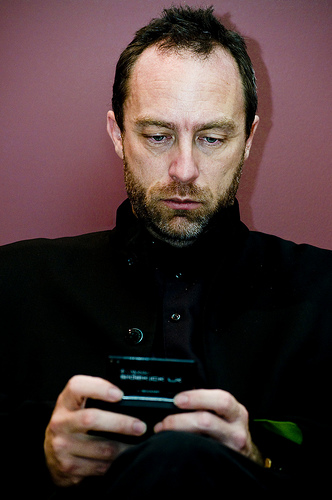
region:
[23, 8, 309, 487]
a man holding an electronic device in his hand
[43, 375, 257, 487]
the hands of a man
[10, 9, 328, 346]
a man wearing a black coat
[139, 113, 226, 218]
the face of a man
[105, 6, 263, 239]
the head of a man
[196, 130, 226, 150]
the eye of a man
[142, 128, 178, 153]
the eye of a man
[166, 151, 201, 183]
the nose of a man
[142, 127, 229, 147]
the eyes of a man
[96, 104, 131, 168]
the ear of a man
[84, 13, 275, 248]
man has a beard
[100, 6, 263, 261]
man has blue eyes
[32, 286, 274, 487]
man is holding a device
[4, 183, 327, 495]
man is wearing a black coat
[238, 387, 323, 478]
jacket has green pocket liner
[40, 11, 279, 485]
man is looking at device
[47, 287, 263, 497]
device is in man's hands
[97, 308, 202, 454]
device has blue lights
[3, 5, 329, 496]
man is staring intently at device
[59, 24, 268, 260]
the head of a man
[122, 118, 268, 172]
the eyes of a man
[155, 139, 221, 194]
the nose of a man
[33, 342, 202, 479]
the hand of a man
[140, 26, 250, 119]
the forehead of a man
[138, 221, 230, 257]
the chin of a man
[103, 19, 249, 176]
the hair of a man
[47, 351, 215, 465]
the fingers of a man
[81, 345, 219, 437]
man holding a phone.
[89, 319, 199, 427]
the phone is black.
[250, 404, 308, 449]
green fabric on the man.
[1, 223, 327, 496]
man's coat is black.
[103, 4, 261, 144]
man's hair is brown.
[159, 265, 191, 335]
buttons on man's shirt.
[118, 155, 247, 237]
man has a beard.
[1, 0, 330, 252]
the wall is burgundy.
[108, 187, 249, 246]
the coat is a turtle neck.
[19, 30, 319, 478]
man sitting down looking at phone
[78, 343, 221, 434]
sideways flip-up phone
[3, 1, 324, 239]
mauve walls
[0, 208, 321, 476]
man wearing black jacket with green lining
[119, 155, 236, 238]
man has beard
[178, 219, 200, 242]
a patch of grey in the man's beard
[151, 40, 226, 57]
man's hair line is receding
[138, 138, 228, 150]
bags under his eyes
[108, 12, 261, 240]
man has a serious expression on his face